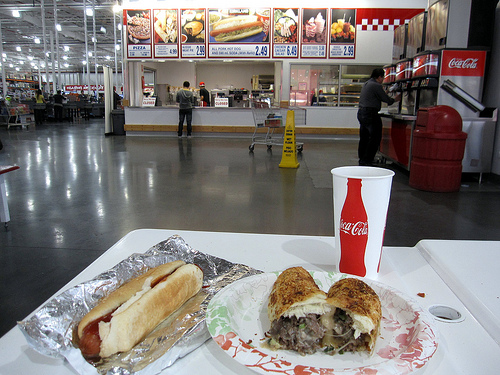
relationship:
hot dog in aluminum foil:
[78, 260, 211, 362] [16, 234, 264, 374]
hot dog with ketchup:
[78, 260, 211, 362] [92, 265, 187, 333]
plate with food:
[205, 263, 439, 369] [261, 262, 383, 360]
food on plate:
[261, 262, 383, 360] [205, 263, 439, 369]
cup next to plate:
[329, 164, 395, 272] [205, 263, 439, 369]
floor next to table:
[4, 118, 500, 324] [2, 225, 499, 372]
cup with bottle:
[329, 164, 395, 272] [338, 181, 371, 281]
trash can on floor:
[404, 103, 475, 193] [4, 118, 500, 324]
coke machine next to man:
[383, 47, 492, 170] [357, 63, 407, 166]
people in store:
[109, 62, 407, 169] [6, 5, 500, 373]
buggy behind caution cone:
[245, 90, 314, 158] [277, 111, 300, 169]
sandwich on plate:
[268, 263, 389, 357] [205, 263, 439, 369]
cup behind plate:
[329, 164, 395, 272] [205, 263, 439, 369]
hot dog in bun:
[78, 260, 211, 362] [81, 261, 189, 359]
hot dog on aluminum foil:
[78, 260, 211, 362] [16, 234, 264, 374]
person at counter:
[175, 82, 197, 140] [126, 92, 271, 111]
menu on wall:
[116, 5, 358, 62] [117, 0, 474, 143]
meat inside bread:
[275, 310, 370, 347] [260, 262, 384, 350]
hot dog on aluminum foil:
[78, 260, 211, 362] [77, 259, 206, 366]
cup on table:
[329, 164, 395, 272] [2, 225, 499, 372]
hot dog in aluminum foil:
[78, 260, 211, 362] [77, 259, 206, 366]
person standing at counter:
[175, 77, 206, 137] [126, 103, 356, 113]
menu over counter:
[116, 5, 358, 62] [126, 103, 356, 113]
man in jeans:
[357, 63, 407, 166] [176, 110, 194, 135]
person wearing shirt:
[175, 82, 197, 140] [170, 88, 197, 111]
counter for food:
[126, 92, 271, 111] [116, 5, 358, 62]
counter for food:
[126, 92, 271, 111] [261, 262, 383, 360]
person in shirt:
[175, 77, 206, 137] [172, 88, 199, 111]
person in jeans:
[175, 77, 206, 137] [178, 114, 194, 135]